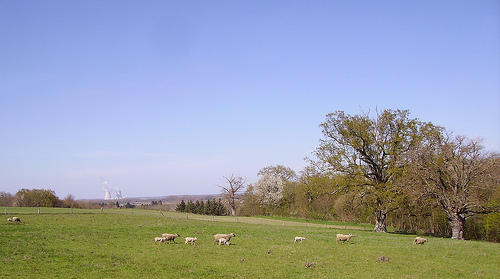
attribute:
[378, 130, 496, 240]
tree — brown, wide, Short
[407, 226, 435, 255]
sheep — tan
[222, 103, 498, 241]
trees — large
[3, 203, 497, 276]
grass — long, green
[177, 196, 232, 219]
trees — tall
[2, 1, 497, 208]
sky — blue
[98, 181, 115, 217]
tower — white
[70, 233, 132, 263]
grass — green 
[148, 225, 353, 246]
sheep — walking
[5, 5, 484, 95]
sky — blue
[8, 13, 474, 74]
sky — clear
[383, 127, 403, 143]
leaves — green 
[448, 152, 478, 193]
branches — bare 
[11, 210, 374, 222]
posts — WHITE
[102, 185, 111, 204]
tower — WHITE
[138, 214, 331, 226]
pathway — CLEARED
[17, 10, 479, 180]
sky — CLEAR, BLUE